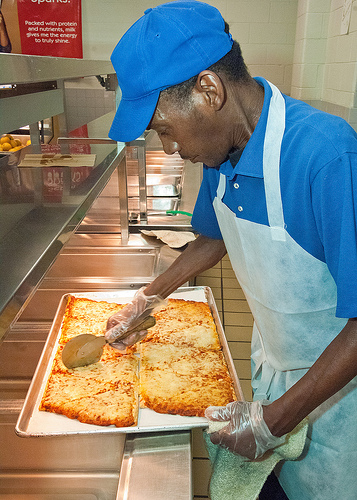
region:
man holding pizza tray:
[51, 278, 271, 452]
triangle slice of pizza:
[144, 374, 234, 414]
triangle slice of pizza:
[74, 356, 136, 389]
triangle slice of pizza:
[43, 366, 115, 403]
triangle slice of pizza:
[51, 385, 141, 431]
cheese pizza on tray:
[62, 293, 226, 426]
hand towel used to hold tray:
[201, 399, 315, 499]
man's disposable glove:
[203, 402, 287, 463]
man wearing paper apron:
[177, 105, 352, 494]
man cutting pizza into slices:
[31, 268, 248, 457]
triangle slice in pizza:
[60, 387, 139, 423]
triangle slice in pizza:
[43, 363, 118, 409]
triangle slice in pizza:
[69, 357, 139, 383]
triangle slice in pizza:
[163, 377, 240, 420]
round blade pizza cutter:
[54, 307, 163, 365]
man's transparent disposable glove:
[202, 394, 283, 466]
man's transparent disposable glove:
[95, 278, 178, 351]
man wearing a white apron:
[177, 71, 354, 493]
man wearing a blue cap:
[98, 5, 257, 143]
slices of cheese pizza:
[148, 307, 238, 416]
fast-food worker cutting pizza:
[13, 14, 355, 497]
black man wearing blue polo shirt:
[107, 13, 354, 498]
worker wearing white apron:
[107, 13, 356, 497]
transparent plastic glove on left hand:
[206, 401, 286, 459]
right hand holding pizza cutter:
[61, 286, 154, 368]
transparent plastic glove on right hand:
[105, 285, 167, 351]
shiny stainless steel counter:
[1, 133, 131, 337]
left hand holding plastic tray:
[15, 287, 279, 461]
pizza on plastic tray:
[12, 284, 239, 438]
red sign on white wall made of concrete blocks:
[0, 12, 294, 96]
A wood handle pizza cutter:
[56, 306, 164, 370]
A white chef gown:
[208, 70, 348, 490]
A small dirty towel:
[196, 411, 309, 490]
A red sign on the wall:
[7, 0, 80, 59]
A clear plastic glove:
[197, 392, 279, 456]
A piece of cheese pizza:
[51, 352, 138, 383]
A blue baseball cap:
[98, 0, 234, 142]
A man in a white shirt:
[105, 0, 351, 497]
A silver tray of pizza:
[9, 279, 246, 439]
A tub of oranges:
[0, 131, 46, 153]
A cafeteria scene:
[0, 0, 355, 498]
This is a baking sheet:
[14, 283, 246, 436]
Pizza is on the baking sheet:
[37, 293, 234, 428]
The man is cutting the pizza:
[37, 0, 356, 498]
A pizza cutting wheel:
[60, 314, 156, 370]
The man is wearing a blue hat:
[107, 1, 237, 168]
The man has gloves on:
[103, 285, 286, 461]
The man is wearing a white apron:
[211, 79, 355, 498]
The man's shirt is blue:
[189, 74, 356, 321]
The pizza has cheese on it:
[38, 293, 236, 427]